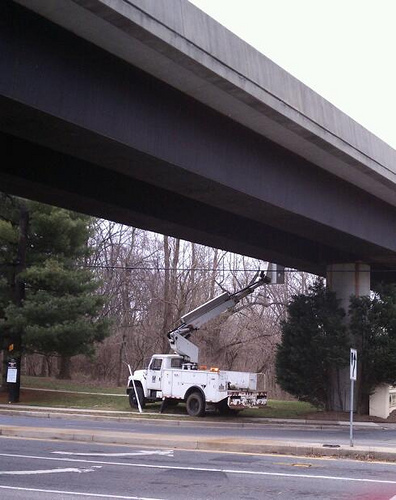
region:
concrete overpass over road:
[256, 52, 352, 490]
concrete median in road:
[73, 422, 394, 467]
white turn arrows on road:
[40, 435, 239, 497]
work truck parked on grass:
[87, 311, 360, 452]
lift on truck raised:
[152, 258, 283, 415]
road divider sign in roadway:
[325, 330, 374, 474]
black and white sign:
[344, 335, 372, 396]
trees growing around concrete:
[275, 275, 387, 433]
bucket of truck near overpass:
[238, 248, 320, 305]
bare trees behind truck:
[101, 230, 179, 418]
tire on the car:
[173, 386, 212, 419]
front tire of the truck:
[127, 385, 156, 408]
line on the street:
[180, 456, 215, 491]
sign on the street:
[323, 343, 372, 429]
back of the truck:
[209, 363, 270, 415]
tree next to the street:
[44, 264, 94, 323]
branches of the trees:
[113, 276, 158, 305]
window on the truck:
[146, 353, 169, 378]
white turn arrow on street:
[118, 439, 168, 480]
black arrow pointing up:
[341, 342, 373, 381]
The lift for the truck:
[163, 271, 263, 363]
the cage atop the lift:
[259, 261, 288, 285]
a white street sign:
[343, 341, 360, 445]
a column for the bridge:
[319, 265, 372, 412]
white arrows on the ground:
[10, 437, 181, 499]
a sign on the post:
[6, 359, 19, 383]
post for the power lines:
[1, 212, 41, 398]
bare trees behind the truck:
[108, 274, 161, 349]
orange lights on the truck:
[188, 361, 227, 374]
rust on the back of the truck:
[221, 386, 276, 413]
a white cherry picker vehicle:
[122, 264, 284, 420]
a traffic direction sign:
[346, 345, 359, 450]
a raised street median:
[0, 421, 394, 461]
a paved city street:
[0, 437, 395, 498]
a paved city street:
[1, 410, 389, 443]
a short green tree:
[275, 289, 348, 408]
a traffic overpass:
[1, 0, 393, 275]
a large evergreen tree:
[0, 201, 104, 400]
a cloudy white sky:
[196, 0, 392, 147]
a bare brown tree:
[150, 237, 182, 353]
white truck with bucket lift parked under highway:
[120, 251, 293, 419]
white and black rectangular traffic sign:
[343, 342, 361, 452]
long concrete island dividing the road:
[0, 420, 394, 462]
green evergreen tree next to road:
[2, 162, 117, 413]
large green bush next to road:
[271, 247, 394, 418]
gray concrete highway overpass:
[0, 0, 395, 307]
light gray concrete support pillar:
[318, 247, 376, 418]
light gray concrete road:
[0, 403, 395, 498]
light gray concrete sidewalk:
[0, 400, 395, 431]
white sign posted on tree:
[3, 353, 26, 386]